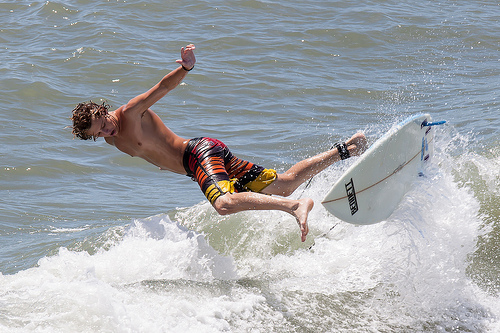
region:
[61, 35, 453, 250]
surfboard dude caught in mid wipeout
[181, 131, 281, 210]
surfboard dude is wearing multicolored trunks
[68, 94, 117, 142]
surfboard dude has wet curly hair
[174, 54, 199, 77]
surfboard dude is wearing a watch or bracelet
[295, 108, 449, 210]
surfboard dude is fastened by a cord to his board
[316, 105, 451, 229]
surfer dude's surfboard is white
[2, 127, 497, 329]
the wave doesn't look very high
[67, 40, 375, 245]
surfboard dude is not wearing a shirt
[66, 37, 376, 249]
surfboard dude is about to crash into the water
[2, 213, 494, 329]
the crashing wave churning up white foam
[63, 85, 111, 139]
head of a person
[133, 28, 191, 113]
arm of a person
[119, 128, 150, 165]
chest of a person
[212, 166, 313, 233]
leg of a person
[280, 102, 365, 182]
leg of a person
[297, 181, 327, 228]
feet of a person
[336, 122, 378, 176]
feet of a person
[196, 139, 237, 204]
thigh of a person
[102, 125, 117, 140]
nose of a person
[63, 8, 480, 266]
a person on a board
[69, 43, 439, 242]
A man falling off of a surfboard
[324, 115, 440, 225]
Underside of a surfboard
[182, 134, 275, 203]
Colorful trunks on a surfer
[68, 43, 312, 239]
A man in midair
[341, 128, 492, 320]
Water splashing off of a surfboard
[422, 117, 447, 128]
Blue fin on the underside of a surfboard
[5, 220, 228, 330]
Water splashing as a wave crashes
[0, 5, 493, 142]
Grayish water in the ocean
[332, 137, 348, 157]
A band around a man's ankle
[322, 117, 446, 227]
White surfboard in the water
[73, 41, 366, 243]
a man falling from a surfboard into the ocean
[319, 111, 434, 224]
a white surfboard on the water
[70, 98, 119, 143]
man with curly brown wet hair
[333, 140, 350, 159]
man wearing an ankle band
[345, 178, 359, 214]
a black logo on a white surfboard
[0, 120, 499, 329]
a wave in the ocean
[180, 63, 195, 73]
man wearing a watch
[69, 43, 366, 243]
a man falling sideways in the water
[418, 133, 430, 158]
a blue logo on a surfboard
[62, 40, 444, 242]
ATHLETIC PERSON ON SURFBOARD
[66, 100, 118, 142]
HEAD OF ATHLETIC SURFER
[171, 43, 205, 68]
HAND OF ATHLETIC SURFER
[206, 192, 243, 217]
KNEE OF ATHLETIC SURFER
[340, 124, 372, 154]
FOOT OF ATHLETIC SURFER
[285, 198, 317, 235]
FOOT OF ATHLETIC SURFER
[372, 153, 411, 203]
PART OF BOTTOM OF SURFBOARDER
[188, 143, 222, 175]
PART OF BRIGHT COLORED PANTS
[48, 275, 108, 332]
WHITE CHURNING SURF WATER